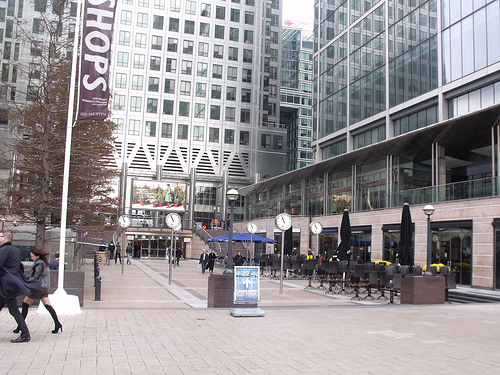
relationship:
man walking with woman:
[3, 232, 37, 343] [19, 248, 64, 333]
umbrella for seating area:
[399, 196, 414, 261] [262, 254, 452, 305]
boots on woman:
[16, 302, 76, 339] [21, 234, 68, 342]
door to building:
[157, 238, 167, 261] [0, 12, 290, 258]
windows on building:
[118, 0, 255, 146] [1, 0, 291, 230]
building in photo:
[93, 4, 285, 246] [7, 9, 499, 362]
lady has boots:
[13, 250, 62, 334] [15, 301, 66, 335]